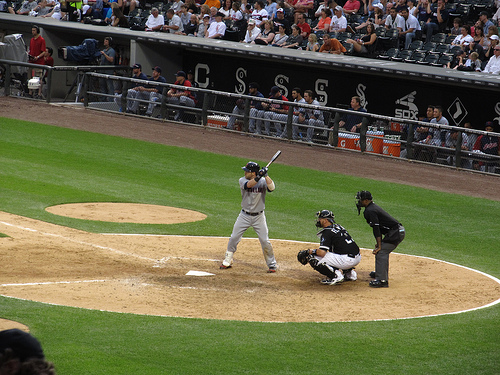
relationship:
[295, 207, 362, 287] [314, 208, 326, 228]
catcher has on helmet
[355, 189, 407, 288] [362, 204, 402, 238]
umpire has on shirt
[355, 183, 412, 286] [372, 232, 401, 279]
umpire wearing pants